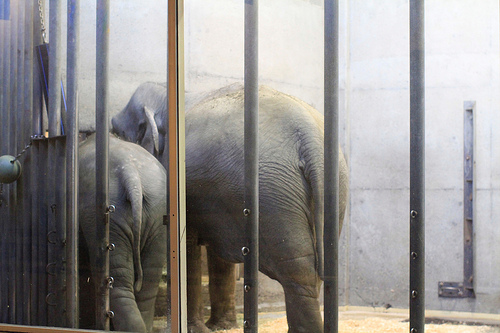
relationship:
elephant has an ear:
[111, 82, 349, 333] [130, 93, 172, 162]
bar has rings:
[243, 0, 260, 333] [234, 195, 255, 321]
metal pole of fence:
[234, 0, 271, 330] [80, 5, 450, 322]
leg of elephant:
[266, 248, 354, 331] [116, 67, 387, 327]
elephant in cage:
[111, 82, 349, 333] [15, 13, 465, 311]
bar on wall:
[462, 101, 476, 301] [61, 20, 496, 321]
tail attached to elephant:
[117, 178, 156, 293] [88, 131, 188, 313]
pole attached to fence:
[399, 26, 431, 331] [2, 25, 474, 328]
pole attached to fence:
[309, 14, 347, 324] [2, 25, 474, 328]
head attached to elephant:
[110, 83, 174, 151] [111, 82, 349, 333]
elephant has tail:
[111, 82, 349, 333] [298, 132, 328, 280]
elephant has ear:
[111, 82, 349, 333] [133, 103, 165, 156]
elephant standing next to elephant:
[111, 82, 349, 333] [77, 126, 169, 332]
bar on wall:
[437, 99, 480, 301] [79, 5, 499, 310]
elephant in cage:
[107, 79, 357, 328] [3, 3, 499, 332]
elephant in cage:
[77, 126, 169, 332] [3, 3, 499, 332]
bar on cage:
[242, 0, 261, 331] [3, 3, 499, 332]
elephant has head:
[111, 82, 349, 333] [112, 77, 172, 150]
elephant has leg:
[111, 82, 349, 333] [207, 248, 238, 331]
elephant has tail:
[77, 126, 169, 332] [121, 162, 147, 298]